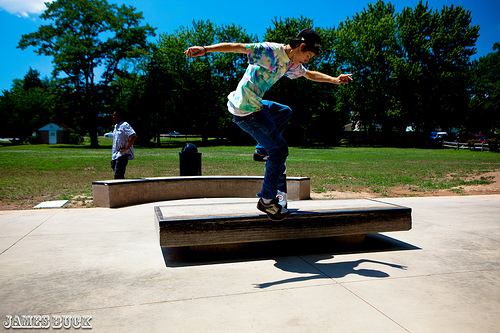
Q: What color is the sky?
A: Blue.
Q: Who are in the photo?
A: People.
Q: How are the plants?
A: Green.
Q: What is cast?
A: Shadow.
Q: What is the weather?
A: Sunny.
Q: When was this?
A: Daytime.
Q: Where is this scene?
A: Skatepark.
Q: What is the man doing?
A: Skating.